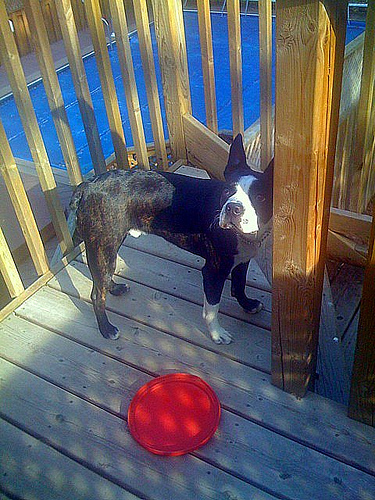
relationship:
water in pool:
[1, 17, 363, 185] [0, 4, 371, 186]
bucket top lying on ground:
[127, 373, 221, 457] [1, 154, 373, 497]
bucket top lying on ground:
[127, 373, 221, 457] [21, 214, 361, 490]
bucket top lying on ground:
[127, 373, 221, 457] [32, 338, 360, 481]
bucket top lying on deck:
[127, 373, 221, 457] [0, 0, 373, 498]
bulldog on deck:
[69, 133, 274, 347] [1, 159, 373, 499]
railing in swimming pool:
[183, 0, 357, 19] [0, 5, 274, 192]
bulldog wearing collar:
[69, 133, 274, 347] [231, 223, 272, 250]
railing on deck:
[0, 1, 372, 425] [0, 0, 373, 498]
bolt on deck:
[331, 331, 340, 342] [0, 0, 373, 498]